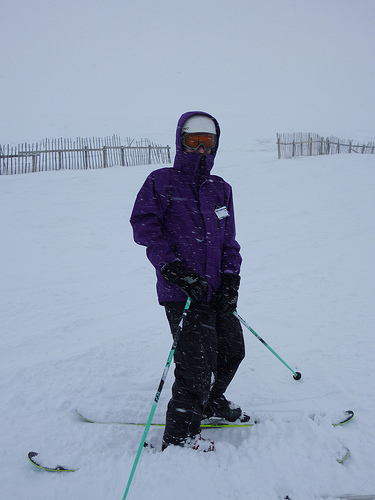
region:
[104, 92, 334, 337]
a person that is skiing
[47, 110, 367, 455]
a person on skies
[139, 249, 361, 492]
a person holding ski poles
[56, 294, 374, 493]
a person standing on skies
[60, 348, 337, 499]
skies covered in snow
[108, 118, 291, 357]
a purple jacket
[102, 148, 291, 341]
a person wearing a jakcet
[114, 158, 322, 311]
a person wearing a purple jacket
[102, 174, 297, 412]
a person wearing pants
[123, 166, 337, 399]
a person wearing gloves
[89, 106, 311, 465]
a person skiing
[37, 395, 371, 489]
skis covered in snow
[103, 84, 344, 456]
a person holding ski poles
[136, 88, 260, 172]
a person wearing ski goggles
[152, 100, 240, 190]
a person wearing a hood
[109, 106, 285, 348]
a person wearing black gloves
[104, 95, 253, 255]
a person wearing a white helmet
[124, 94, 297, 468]
a person wearing black ski pants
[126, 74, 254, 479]
a person wearing ski boots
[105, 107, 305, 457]
person wearing purple jacket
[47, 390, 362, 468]
ski under snow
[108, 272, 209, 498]
person holding a snow stick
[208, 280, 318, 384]
person holding snow stick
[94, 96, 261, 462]
person wearing a snow goggle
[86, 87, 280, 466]
person wearing a pair of glove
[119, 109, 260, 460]
person wearing a tag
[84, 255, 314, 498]
person holding two snow sticks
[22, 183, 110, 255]
white snowy field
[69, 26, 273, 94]
a sky full of snow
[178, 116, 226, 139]
Person wearing helmet on head.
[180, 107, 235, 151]
Helmet on head is white.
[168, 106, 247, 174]
Purple hood on jacket.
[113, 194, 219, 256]
Person wearing purple jacket.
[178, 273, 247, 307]
Person wearing black gloves.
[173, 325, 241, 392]
Person wearing black pants.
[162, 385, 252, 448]
Person wearing black boots.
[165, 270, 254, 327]
Person holding ski poles.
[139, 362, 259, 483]
Person has skis on feet.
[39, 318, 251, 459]
Ground is covered in snow.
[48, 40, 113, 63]
a clear white sky.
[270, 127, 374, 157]
a long brown fence.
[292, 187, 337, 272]
a sidewalk full of white snow.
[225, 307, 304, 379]
a green and black ski stick.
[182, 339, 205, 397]
a man is wearing black pants.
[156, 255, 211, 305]
a man is wearing a pair of black gloves.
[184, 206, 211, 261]
a man is wearing a dark purple jacket.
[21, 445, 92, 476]
a light green ski shoe.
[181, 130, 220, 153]
a man is wearing brown goggles.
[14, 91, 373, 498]
a man is going skiing in the snow.